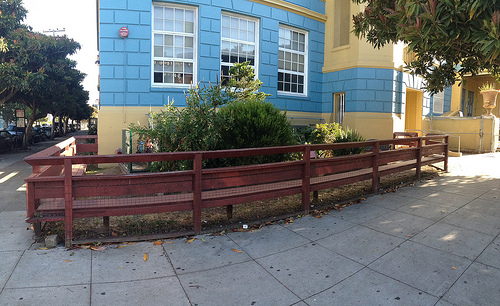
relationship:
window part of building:
[219, 10, 255, 92] [94, 0, 499, 171]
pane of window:
[146, 76, 311, 98] [149, 0, 324, 98]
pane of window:
[165, 31, 175, 44] [140, 26, 204, 97]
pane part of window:
[154, 37, 161, 59] [150, 0, 201, 84]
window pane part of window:
[291, 52, 299, 70] [279, 22, 309, 97]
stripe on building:
[315, 56, 404, 118] [91, 2, 499, 170]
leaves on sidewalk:
[37, 168, 447, 265] [1, 156, 500, 306]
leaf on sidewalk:
[140, 250, 147, 262] [1, 247, 497, 302]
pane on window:
[135, 13, 220, 98] [150, 2, 198, 90]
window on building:
[149, 0, 197, 89] [94, 0, 499, 171]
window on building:
[219, 10, 255, 92] [94, 0, 499, 171]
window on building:
[278, 25, 307, 90] [94, 0, 499, 171]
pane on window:
[163, 60, 175, 73] [150, 2, 198, 90]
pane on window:
[278, 72, 284, 81] [275, 29, 307, 94]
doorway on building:
[404, 87, 423, 147] [94, 0, 499, 171]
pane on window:
[165, 31, 175, 44] [157, 5, 194, 92]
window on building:
[134, 6, 205, 103] [73, 8, 490, 183]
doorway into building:
[400, 85, 424, 147] [91, 2, 499, 170]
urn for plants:
[470, 80, 498, 117] [118, 63, 375, 201]